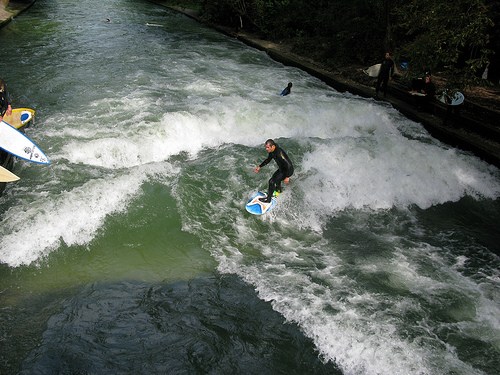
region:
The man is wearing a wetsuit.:
[253, 134, 295, 206]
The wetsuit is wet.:
[251, 134, 297, 206]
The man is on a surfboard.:
[239, 134, 300, 221]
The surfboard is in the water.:
[133, 131, 438, 280]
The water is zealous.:
[1, 2, 499, 374]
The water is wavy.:
[0, 0, 499, 374]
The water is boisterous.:
[1, 1, 498, 369]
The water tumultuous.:
[0, 2, 497, 372]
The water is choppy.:
[3, 1, 499, 373]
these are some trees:
[318, 0, 485, 52]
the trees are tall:
[367, 1, 487, 44]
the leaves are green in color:
[426, 15, 480, 65]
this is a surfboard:
[1, 122, 49, 165]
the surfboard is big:
[0, 116, 52, 171]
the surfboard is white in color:
[3, 130, 14, 140]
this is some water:
[73, 192, 225, 236]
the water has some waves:
[331, 194, 433, 305]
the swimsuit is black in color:
[278, 161, 287, 168]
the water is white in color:
[310, 107, 344, 119]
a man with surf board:
[236, 127, 306, 234]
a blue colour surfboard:
[243, 179, 293, 216]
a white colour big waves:
[41, 90, 480, 244]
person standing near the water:
[370, 46, 412, 98]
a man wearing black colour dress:
[267, 151, 294, 200]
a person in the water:
[271, 71, 301, 116]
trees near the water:
[347, 20, 489, 70]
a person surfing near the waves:
[218, 130, 418, 238]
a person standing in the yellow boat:
[0, 80, 45, 130]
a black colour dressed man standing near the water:
[370, 42, 398, 102]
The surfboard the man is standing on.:
[237, 186, 290, 215]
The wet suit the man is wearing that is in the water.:
[260, 155, 290, 202]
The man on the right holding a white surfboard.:
[362, 48, 403, 110]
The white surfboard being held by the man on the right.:
[361, 60, 384, 76]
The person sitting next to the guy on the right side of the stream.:
[410, 68, 436, 105]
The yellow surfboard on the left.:
[5, 97, 45, 130]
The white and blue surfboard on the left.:
[4, 118, 56, 171]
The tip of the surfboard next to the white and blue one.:
[2, 162, 28, 191]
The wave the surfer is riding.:
[82, 145, 410, 272]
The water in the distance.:
[14, 22, 375, 172]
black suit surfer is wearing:
[269, 152, 294, 202]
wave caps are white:
[279, 209, 417, 370]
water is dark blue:
[44, 290, 309, 373]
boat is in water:
[0, 132, 62, 164]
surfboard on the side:
[407, 80, 489, 120]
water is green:
[43, 200, 208, 277]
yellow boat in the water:
[3, 103, 39, 128]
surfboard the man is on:
[247, 198, 269, 212]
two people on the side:
[365, 51, 444, 115]